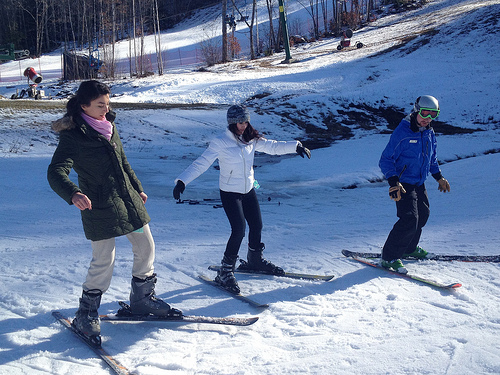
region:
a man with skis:
[344, 79, 496, 299]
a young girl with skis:
[170, 100, 341, 309]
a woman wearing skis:
[44, 75, 202, 364]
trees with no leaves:
[42, 2, 192, 92]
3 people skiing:
[50, 76, 477, 336]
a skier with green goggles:
[342, 87, 483, 305]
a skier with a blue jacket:
[361, 97, 475, 305]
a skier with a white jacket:
[167, 107, 348, 307]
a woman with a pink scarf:
[36, 92, 180, 354]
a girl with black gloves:
[165, 105, 316, 208]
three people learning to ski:
[46, 68, 462, 337]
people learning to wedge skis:
[49, 76, 469, 354]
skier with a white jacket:
[167, 91, 334, 308]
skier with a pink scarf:
[51, 75, 179, 372]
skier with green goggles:
[361, 83, 471, 303]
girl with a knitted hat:
[223, 101, 263, 139]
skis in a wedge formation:
[44, 280, 257, 370]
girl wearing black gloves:
[159, 168, 203, 211]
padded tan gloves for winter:
[382, 176, 464, 205]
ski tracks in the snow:
[287, 285, 397, 335]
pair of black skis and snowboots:
[47, 275, 262, 373]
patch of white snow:
[319, 317, 376, 371]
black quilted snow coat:
[48, 112, 150, 243]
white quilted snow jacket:
[177, 124, 300, 199]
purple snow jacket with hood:
[373, 112, 444, 178]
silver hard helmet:
[413, 95, 440, 114]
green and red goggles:
[413, 105, 442, 120]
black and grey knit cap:
[221, 99, 249, 125]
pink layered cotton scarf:
[78, 112, 116, 141]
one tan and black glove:
[381, 178, 412, 200]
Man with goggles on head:
[414, 96, 439, 121]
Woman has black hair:
[64, 79, 111, 121]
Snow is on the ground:
[1, 295, 498, 372]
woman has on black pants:
[218, 190, 270, 258]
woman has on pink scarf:
[76, 112, 114, 139]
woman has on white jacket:
[179, 127, 296, 191]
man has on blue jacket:
[378, 112, 443, 185]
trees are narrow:
[6, 0, 163, 81]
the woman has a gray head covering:
[226, 100, 247, 122]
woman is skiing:
[46, 79, 171, 336]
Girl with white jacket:
[173, 101, 325, 303]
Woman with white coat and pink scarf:
[37, 82, 196, 363]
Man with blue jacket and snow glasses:
[357, 56, 462, 305]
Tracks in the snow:
[282, 281, 357, 372]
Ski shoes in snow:
[32, 279, 246, 374]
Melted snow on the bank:
[262, 72, 416, 177]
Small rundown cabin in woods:
[58, 39, 124, 79]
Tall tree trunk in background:
[212, 9, 262, 80]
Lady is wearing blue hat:
[222, 102, 251, 135]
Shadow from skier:
[0, 280, 168, 369]